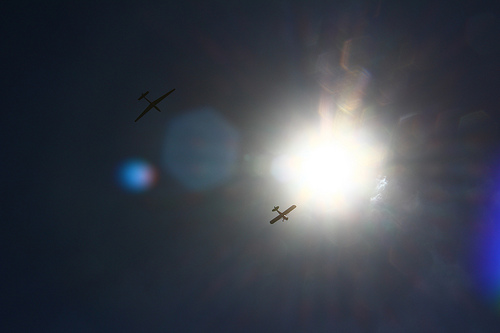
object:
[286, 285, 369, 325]
no objects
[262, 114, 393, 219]
sun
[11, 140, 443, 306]
sky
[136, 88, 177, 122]
airplane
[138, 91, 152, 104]
tail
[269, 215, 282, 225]
wings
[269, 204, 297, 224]
airplane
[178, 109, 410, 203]
sun spots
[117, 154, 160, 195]
spot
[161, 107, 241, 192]
spot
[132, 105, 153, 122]
wing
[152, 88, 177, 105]
wing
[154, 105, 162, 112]
nose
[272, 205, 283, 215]
tail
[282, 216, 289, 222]
nose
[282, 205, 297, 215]
wing